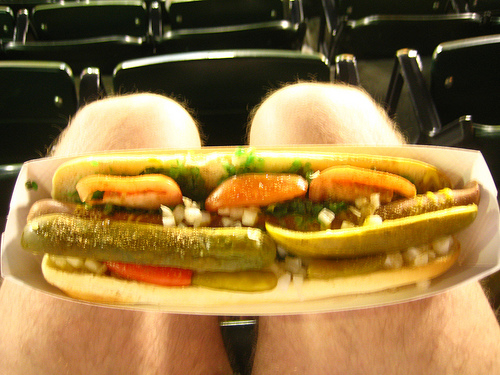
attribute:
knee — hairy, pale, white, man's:
[49, 92, 201, 155]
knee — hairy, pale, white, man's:
[248, 81, 404, 146]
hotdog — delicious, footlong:
[26, 182, 481, 231]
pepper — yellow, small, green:
[195, 271, 278, 291]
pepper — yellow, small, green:
[305, 253, 387, 276]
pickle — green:
[21, 214, 275, 272]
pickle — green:
[266, 205, 479, 258]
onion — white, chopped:
[186, 208, 200, 221]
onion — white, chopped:
[318, 206, 333, 225]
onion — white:
[367, 215, 383, 226]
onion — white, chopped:
[159, 202, 173, 215]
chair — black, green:
[78, 50, 363, 147]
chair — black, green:
[385, 36, 500, 146]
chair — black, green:
[1, 62, 108, 164]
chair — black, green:
[319, 1, 484, 59]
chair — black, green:
[152, 4, 307, 48]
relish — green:
[139, 166, 208, 205]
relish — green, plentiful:
[274, 197, 349, 229]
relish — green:
[220, 146, 317, 183]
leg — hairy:
[2, 278, 231, 374]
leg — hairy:
[250, 279, 499, 373]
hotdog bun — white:
[41, 152, 457, 308]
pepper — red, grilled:
[106, 259, 194, 288]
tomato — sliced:
[76, 173, 182, 213]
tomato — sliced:
[207, 172, 307, 210]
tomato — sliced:
[305, 166, 417, 202]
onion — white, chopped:
[230, 209, 246, 219]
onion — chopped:
[412, 253, 426, 264]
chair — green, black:
[5, 2, 163, 55]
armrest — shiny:
[386, 48, 440, 133]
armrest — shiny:
[334, 54, 360, 87]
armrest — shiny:
[78, 68, 107, 103]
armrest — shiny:
[150, 3, 162, 36]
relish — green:
[26, 181, 37, 191]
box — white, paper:
[2, 144, 499, 318]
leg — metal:
[384, 66, 403, 121]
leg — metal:
[315, 12, 328, 53]